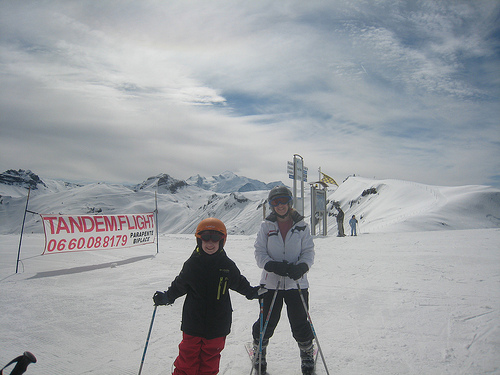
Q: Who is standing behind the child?
A: Woman in white jacket.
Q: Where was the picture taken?
A: On a ski slope.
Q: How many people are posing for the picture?
A: 2.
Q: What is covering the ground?
A: Snow.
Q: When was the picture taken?
A: Winter.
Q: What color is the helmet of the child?
A: Orange.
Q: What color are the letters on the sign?
A: Red.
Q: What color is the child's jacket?
A: Black.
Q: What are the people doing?
A: Skiing.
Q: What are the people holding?
A: Ski poles.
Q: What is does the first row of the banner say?
A: Tandem.Flight.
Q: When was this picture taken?
A: Daytime.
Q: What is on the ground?
A: Snow.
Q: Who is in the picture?
A: A woman and a child.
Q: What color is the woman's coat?
A: White.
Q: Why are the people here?
A: To ski.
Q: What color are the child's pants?
A: Red.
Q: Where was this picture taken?
A: The ski slope.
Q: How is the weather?
A: Cloudy.